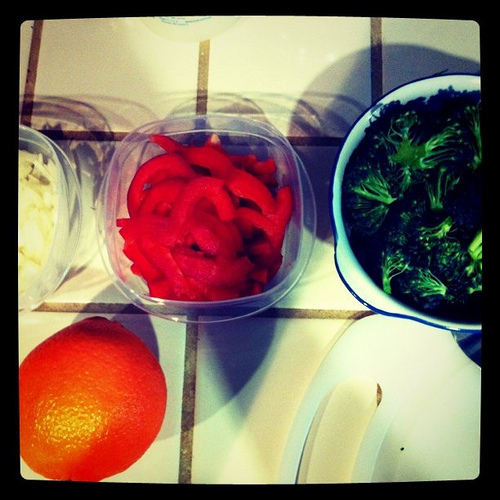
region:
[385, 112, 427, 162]
PART OF BROCCOLI SPEAR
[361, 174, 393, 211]
PART OF BROCCOLI SPEAR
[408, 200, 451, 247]
PART OF BROCCOLI SPEAR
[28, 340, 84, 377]
PART OF FRESH ORANGE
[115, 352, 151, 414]
PART OF FRESH ORANGE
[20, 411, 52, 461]
PAT OF FRESH ORANGE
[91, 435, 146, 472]
PART OF FRESH ORANGE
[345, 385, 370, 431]
PART OF FRESH BANANA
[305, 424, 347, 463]
PART OF FRESH BANANA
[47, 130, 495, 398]
this is healthy food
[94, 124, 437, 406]
these are vegetables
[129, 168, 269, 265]
these peppers are sliced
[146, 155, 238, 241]
the peppers are red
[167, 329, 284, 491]
the countertop is tile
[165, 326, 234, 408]
the counter is gray and white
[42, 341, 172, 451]
this is a fruit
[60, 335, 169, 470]
this is an orange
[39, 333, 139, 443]
the fruit is orange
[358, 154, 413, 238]
these are broccoli pieces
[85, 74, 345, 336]
this is a bowl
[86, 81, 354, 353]
the bowl is plastic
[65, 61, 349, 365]
the bowl is clear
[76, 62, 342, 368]
food is in the bowl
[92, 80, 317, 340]
bell peppers in the bowl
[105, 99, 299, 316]
bell peppers are red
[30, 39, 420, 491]
bowl sitting on tiles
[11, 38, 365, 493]
grey grout lines around tile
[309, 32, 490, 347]
this is a white bowl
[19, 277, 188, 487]
this is an orange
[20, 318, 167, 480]
orange tangerine-like fruit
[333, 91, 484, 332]
white and blue dish of broccoli crowns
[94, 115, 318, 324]
clear square shaped plastic container with red pepper slices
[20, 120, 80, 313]
partial clear plastic dish with diced onions in it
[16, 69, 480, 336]
three dishes with food in them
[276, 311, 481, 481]
partial flat blue and white cutting board with handle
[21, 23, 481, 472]
off white counter top with brown stripes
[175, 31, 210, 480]
brown line underneath dish of sliced peppers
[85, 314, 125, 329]
top (or bottom) of an orange type fruit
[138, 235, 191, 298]
a slice of bright red bell pepper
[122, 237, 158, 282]
a slice of bright red bell pepper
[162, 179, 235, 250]
a slice of bright red bell pepper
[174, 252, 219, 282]
a slice of bright red bell pepper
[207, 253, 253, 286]
a slice of bright red bell pepper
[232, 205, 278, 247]
a slice of bright red bell pepper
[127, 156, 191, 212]
a slice of bright red bell pepper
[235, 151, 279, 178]
a slice of bright red bell pepper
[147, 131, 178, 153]
a slice of bright red bell pepper